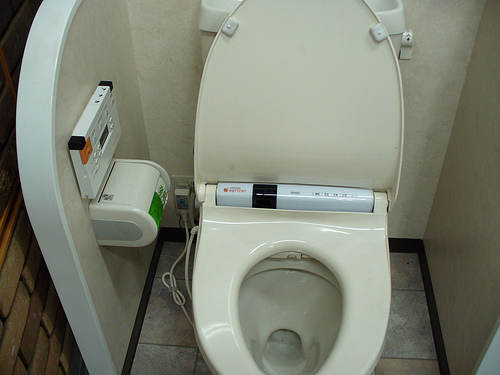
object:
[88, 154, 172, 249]
dispenser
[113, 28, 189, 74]
wall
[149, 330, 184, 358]
floor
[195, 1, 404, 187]
lid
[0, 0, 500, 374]
toilet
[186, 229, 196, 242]
gadget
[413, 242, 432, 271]
baseboard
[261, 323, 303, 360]
hole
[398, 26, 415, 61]
flusher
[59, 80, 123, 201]
control board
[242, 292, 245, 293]
water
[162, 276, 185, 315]
wire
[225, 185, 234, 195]
numbers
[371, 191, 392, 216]
hinge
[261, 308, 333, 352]
bowl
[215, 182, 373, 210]
electronics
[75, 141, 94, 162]
label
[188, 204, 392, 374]
seat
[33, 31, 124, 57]
stall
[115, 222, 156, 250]
toilet paper